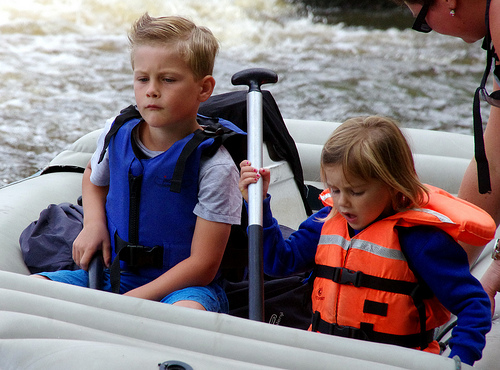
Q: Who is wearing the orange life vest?
A: Girl with blonde hair.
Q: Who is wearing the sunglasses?
A: Woman behind little girl.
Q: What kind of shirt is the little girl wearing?
A: Long sleeved blue shirt.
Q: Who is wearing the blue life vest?
A: Boy with blonde hair.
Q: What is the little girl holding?
A: Black and metal raft device.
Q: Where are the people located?
A: Body of water.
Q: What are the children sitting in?
A: Grey raft.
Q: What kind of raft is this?
A: Grey inflatable.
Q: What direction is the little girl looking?
A: Downward.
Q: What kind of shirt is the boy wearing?
A: Grey short sleeve t-shirt.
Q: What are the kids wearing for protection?
A: Floating vests.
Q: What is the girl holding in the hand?
A: Paddle pole.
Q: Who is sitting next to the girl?
A: A boy.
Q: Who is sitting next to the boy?
A: A girl.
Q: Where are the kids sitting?
A: A raft.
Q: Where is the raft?
A: In the water.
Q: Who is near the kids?
A: A woman.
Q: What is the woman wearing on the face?
A: Sunglasses.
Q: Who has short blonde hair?
A: The boy.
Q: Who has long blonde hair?
A: The girl.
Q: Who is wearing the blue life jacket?
A: Little boy with blonde hair.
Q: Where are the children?
A: Inflatable raft.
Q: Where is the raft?
A: Body of water.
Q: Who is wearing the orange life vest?
A: Little girl with blonde hair.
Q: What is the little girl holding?
A: Metal raft mechanism.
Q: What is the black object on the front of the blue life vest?
A: Black buckle.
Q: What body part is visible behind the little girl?
A: Leg.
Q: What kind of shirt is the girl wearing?
A: Blue long sleeve shirt.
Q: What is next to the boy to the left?
A: Blue bag.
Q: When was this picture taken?
A: Daytime.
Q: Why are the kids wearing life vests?
A: They are near water.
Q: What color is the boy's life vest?
A: Blue.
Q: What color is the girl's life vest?
A: Orange.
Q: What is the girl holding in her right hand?
A: An oar.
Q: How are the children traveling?
A: By boat.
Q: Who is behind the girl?
A: A woman.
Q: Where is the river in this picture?
A: Background.